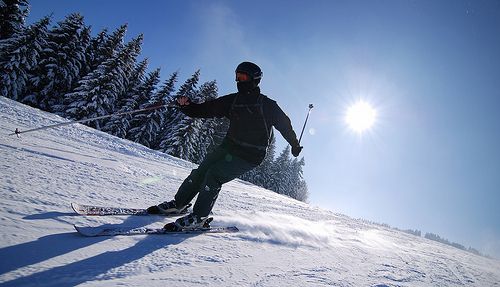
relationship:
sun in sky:
[343, 100, 378, 133] [3, 2, 495, 259]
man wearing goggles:
[147, 61, 303, 233] [227, 70, 256, 86]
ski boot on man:
[156, 198, 186, 213] [147, 61, 303, 233]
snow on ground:
[0, 92, 497, 284] [10, 110, 484, 285]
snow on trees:
[45, 48, 126, 105] [6, 7, 206, 154]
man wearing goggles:
[147, 61, 303, 233] [228, 66, 270, 86]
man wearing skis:
[147, 61, 303, 233] [69, 199, 238, 239]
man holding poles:
[147, 61, 303, 233] [11, 87, 342, 168]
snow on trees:
[33, 41, 108, 111] [46, 30, 158, 158]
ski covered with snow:
[69, 199, 213, 216] [270, 211, 390, 285]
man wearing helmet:
[154, 56, 306, 241] [231, 56, 267, 79]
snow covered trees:
[0, 92, 497, 284] [138, 65, 169, 138]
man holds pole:
[147, 61, 303, 233] [38, 110, 160, 158]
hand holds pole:
[172, 95, 192, 110] [7, 102, 179, 140]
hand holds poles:
[288, 141, 302, 157] [286, 102, 315, 159]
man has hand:
[147, 61, 303, 233] [172, 95, 192, 110]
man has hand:
[147, 61, 303, 233] [288, 141, 302, 157]